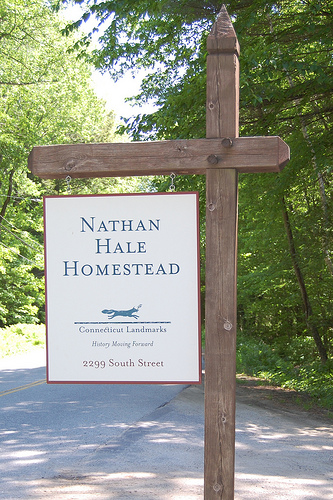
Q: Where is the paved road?
A: Between forests/.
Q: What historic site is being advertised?
A: Nathan Hale Homestead.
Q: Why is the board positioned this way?
A: Sign hangs from.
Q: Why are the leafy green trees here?
A: Grew naturally.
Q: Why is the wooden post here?
A: Part of signage.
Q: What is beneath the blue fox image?
A: Connecticut Landmarks.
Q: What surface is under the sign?
A: Paved road.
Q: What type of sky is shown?
A: Hazy blue.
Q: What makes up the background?
A: Leafy trees.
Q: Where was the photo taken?
A: At a driveway.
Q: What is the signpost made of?
A: Wood.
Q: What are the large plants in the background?
A: Trees.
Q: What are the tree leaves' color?
A: Green.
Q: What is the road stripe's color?
A: Yellow.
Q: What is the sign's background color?
A: White.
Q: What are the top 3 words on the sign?
A: NATHAN HALE HOMESTEAD.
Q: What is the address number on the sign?
A: 2299.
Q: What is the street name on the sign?
A: South Street.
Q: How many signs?
A: One.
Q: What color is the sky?
A: Blue.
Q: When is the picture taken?
A: Daytime.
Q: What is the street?
A: 2299 South Street.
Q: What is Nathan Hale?
A: A homestead.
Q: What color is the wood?
A: Brown.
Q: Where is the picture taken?
A: In a park.